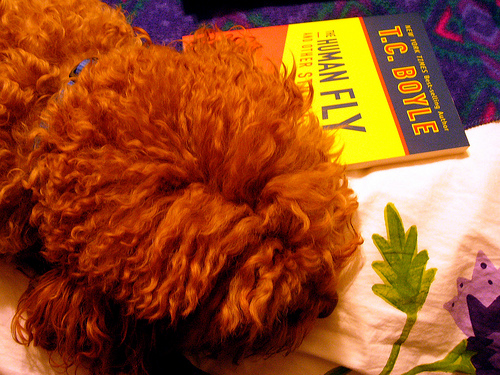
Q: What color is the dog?
A: Red.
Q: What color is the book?
A: Yellow and blue.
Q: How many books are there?
A: One.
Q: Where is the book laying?
A: Blanket.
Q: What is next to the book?
A: Bear.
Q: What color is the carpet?
A: Purple.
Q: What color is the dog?
A: Brown.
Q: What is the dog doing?
A: Sleeping.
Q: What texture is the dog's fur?
A: Fluffy.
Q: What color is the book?
A: Yellow.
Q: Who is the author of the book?
A: TC Boyle.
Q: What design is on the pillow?
A: Leaves.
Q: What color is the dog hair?
A: Reddish brown.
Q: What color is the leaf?
A: Green.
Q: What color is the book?
A: Blue and yellow.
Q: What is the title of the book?
A: The human fly.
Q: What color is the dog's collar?
A: Blue.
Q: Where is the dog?
A: On the bed.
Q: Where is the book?
A: On the bed.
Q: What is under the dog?
A: A bedspread.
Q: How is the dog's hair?
A: Long and shaggy.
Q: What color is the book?
A: Yellow, red, and blue.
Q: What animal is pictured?
A: A dog.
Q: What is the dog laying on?
A: A sheet.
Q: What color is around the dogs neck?
A: Blue.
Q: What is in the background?
A: Book.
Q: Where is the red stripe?
A: Book.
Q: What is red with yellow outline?
A: T. C. Boyle.